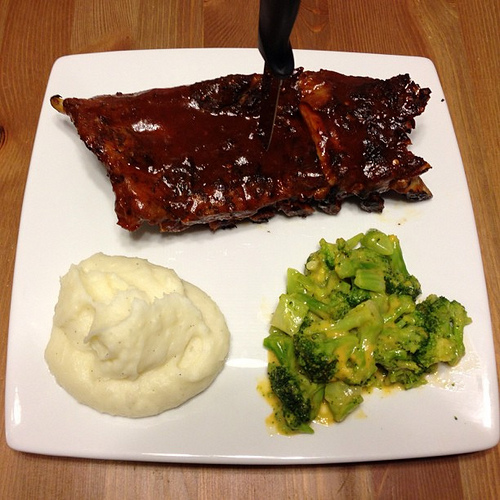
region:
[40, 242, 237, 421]
A pile of mashed potatoes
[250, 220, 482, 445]
A serving of broccoli and cheese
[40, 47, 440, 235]
BBQ ribs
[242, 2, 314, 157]
Knife stuck in a serving of ribs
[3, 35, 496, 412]
White square plate with food on it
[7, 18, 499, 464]
Dinner plate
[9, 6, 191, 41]
Wood table under the plate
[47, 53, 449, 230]
Meat covered in BBQ sauce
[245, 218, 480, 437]
Serving of green vegetables on the plate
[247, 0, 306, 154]
Knife with a black handle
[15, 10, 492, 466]
oblong platter with food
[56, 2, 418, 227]
knife in the center meat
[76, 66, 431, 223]
shiny sauce over ribs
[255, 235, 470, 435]
chopped pieces of broccoli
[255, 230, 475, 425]
green stalks with darker florets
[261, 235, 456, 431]
broccoli coated with cheese sauce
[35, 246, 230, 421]
mound of soft food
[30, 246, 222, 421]
creamy and white heap of vegetable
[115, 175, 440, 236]
bones along side of meat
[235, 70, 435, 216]
dark crust of barbecued meat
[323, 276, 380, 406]
This is a serving of broccoli and cheese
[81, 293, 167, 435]
This is a serving of whipped mashed potatoes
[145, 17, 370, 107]
This is a serving of sassy BBQ ribs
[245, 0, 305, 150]
This is a sharp steak knife in the meat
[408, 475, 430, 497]
The color of this table is a very light brown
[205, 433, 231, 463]
The color of this plate is a very bright white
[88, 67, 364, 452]
This photo was taken in the state of Ilinois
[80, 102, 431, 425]
This photo was taken in the city of Chicago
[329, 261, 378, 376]
This broccoli is dark green in color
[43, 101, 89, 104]
There is a large piece of bone in the ribs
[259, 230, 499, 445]
Broccoli in cheese sauce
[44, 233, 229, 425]
Buttery mashed potatoes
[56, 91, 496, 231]
Half rack of bbq ribs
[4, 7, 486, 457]
White plate full of food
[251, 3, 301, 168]
A black and silver knife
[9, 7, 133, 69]
Part of a wooden table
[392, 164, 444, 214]
Piece of the rib bone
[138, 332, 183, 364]
Little pepper flakes in the potatoes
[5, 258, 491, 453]
Part of a white plate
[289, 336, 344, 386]
Top of the broccoli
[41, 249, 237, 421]
white mashed potatoes on a plate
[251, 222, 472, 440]
green broccoli in yellow sauce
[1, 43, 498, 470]
a white porcelain plate on the table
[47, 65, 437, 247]
brown ribs on a plate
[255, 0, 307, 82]
the black handle of a knife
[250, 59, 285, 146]
the blade of a knife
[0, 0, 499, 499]
a brown wooden table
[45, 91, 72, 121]
a piece of white bone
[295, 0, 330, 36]
a knot in the wood table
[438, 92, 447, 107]
a black speck on the plate